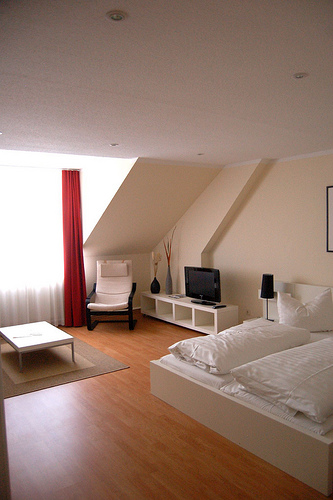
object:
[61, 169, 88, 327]
curtains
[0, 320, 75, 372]
table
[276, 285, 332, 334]
pillow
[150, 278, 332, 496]
bed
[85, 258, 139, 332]
chair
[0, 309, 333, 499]
floor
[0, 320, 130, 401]
carpet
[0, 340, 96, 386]
inner carpet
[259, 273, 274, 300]
lamp shade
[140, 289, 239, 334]
stand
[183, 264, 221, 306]
tv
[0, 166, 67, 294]
window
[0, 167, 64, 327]
sheer curtains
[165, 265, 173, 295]
vase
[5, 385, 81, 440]
light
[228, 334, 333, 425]
linens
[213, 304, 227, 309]
remote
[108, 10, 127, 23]
recessed lighting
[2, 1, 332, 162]
ceiling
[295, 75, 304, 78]
recessed lighting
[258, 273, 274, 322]
lamp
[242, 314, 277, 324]
nightstand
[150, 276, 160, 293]
vases